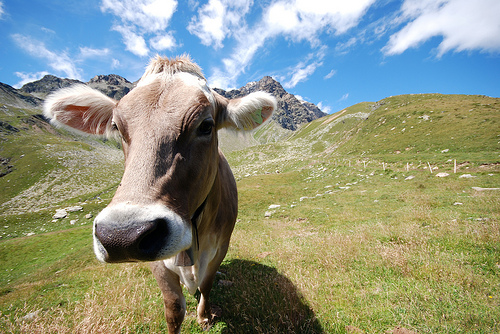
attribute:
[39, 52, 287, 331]
cow — brown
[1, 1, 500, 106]
sky — cloudy, blue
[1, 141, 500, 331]
grass — short, green